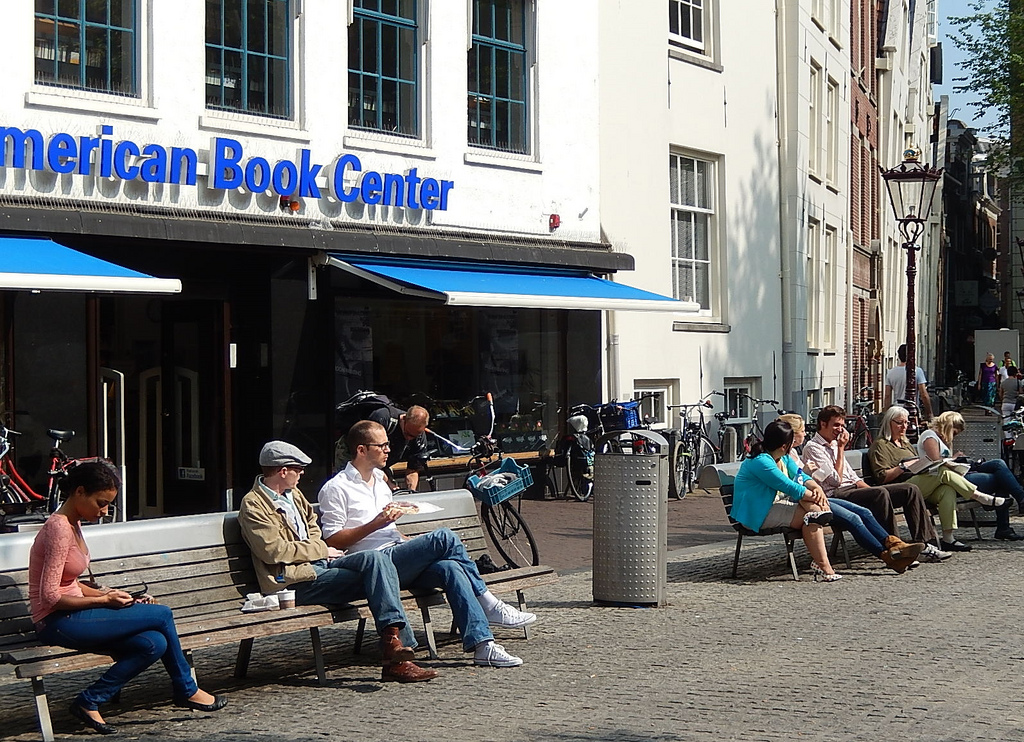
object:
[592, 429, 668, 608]
trashcan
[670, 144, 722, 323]
window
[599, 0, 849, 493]
building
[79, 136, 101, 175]
letters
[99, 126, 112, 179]
letters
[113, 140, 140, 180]
letters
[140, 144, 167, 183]
letters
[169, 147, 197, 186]
letters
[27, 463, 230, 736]
woman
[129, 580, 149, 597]
phone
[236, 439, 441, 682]
men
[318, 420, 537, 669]
men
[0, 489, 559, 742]
bench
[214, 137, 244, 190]
letter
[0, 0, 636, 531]
building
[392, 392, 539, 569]
bicycles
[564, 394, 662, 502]
bicycles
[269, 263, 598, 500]
wall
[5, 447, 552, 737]
bench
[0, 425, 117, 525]
bicycle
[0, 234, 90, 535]
wall